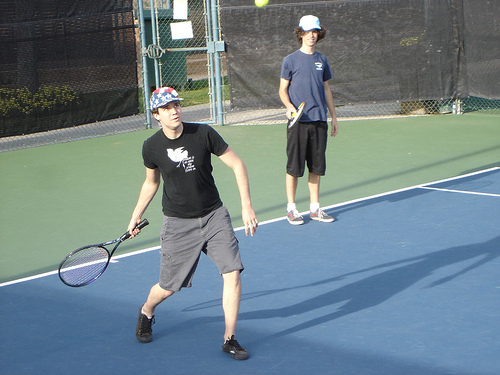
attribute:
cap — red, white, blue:
[146, 87, 183, 107]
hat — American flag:
[151, 86, 185, 110]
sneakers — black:
[221, 334, 250, 361]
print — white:
[161, 144, 218, 194]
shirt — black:
[117, 120, 244, 212]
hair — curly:
[292, 25, 324, 40]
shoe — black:
[222, 334, 249, 361]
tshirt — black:
[138, 122, 229, 224]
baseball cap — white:
[296, 15, 322, 35]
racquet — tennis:
[282, 102, 311, 127]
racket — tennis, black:
[55, 215, 153, 291]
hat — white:
[116, 60, 193, 128]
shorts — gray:
[158, 205, 243, 294]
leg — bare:
[223, 268, 243, 340]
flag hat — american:
[144, 87, 183, 104]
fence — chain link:
[129, 0, 229, 141]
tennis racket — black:
[56, 220, 151, 288]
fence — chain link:
[66, 30, 123, 95]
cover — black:
[13, 14, 147, 159]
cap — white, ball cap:
[296, 10, 326, 32]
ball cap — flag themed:
[146, 85, 184, 111]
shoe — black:
[135, 310, 156, 344]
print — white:
[311, 57, 329, 78]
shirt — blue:
[275, 46, 331, 129]